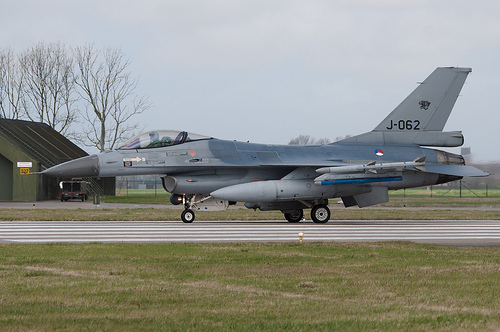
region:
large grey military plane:
[27, 59, 477, 231]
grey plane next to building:
[0, 57, 486, 227]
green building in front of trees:
[0, 28, 156, 218]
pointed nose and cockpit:
[30, 111, 219, 196]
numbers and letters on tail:
[373, 55, 486, 136]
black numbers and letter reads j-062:
[383, 114, 427, 130]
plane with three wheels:
[25, 52, 475, 239]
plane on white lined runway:
[2, 51, 497, 241]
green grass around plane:
[2, 180, 497, 326]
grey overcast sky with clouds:
[10, 0, 499, 191]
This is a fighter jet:
[16, 77, 445, 251]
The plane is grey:
[54, 100, 476, 228]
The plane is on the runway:
[43, 86, 466, 289]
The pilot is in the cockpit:
[121, 104, 278, 190]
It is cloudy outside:
[157, 63, 472, 308]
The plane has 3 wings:
[141, 166, 384, 296]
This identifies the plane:
[357, 89, 452, 181]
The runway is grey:
[61, 215, 466, 254]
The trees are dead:
[19, 52, 214, 192]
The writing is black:
[370, 100, 482, 172]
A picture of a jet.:
[22, 20, 497, 303]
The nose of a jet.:
[25, 141, 108, 188]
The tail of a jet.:
[361, 63, 473, 149]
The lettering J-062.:
[381, 114, 435, 132]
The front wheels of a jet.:
[169, 190, 211, 230]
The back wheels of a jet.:
[270, 194, 352, 230]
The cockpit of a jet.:
[111, 119, 214, 149]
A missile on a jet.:
[309, 150, 436, 188]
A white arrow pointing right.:
[122, 153, 147, 166]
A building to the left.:
[4, 112, 84, 199]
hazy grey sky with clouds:
[5, 5, 498, 165]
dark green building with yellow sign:
[1, 115, 93, 197]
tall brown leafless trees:
[5, 40, 140, 168]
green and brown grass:
[5, 240, 497, 328]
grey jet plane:
[41, 65, 481, 221]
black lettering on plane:
[381, 116, 431, 133]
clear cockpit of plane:
[117, 125, 209, 151]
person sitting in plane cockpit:
[141, 126, 162, 147]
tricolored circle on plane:
[370, 142, 395, 158]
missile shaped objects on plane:
[308, 152, 430, 185]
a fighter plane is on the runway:
[31, 66, 478, 226]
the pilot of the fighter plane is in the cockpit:
[148, 129, 162, 147]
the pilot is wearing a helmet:
[149, 132, 158, 142]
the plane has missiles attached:
[316, 157, 426, 175]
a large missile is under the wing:
[206, 174, 373, 211]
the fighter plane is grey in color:
[48, 67, 483, 226]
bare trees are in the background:
[4, 38, 137, 208]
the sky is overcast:
[6, 6, 498, 180]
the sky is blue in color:
[1, 0, 498, 179]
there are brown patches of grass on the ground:
[1, 241, 497, 329]